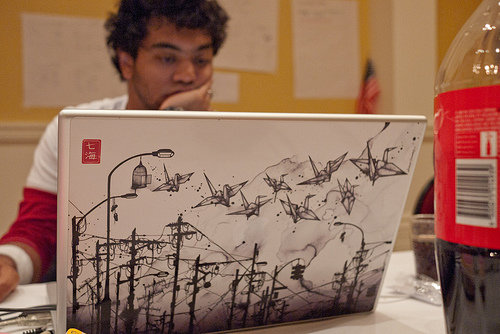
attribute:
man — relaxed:
[0, 1, 231, 301]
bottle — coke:
[431, 1, 499, 333]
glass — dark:
[408, 211, 439, 286]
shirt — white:
[0, 94, 133, 276]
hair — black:
[103, 1, 231, 74]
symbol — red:
[81, 137, 102, 166]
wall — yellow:
[2, 1, 499, 215]